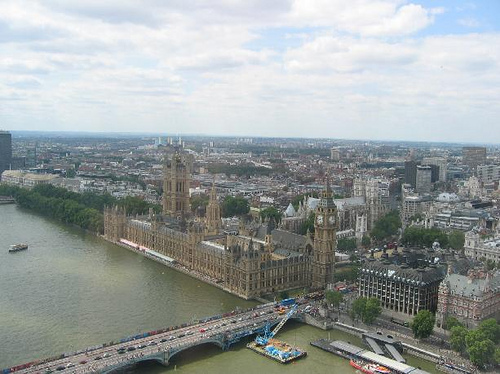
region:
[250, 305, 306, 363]
a tower crane working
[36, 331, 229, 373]
a very busy bridge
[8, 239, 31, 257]
a boat across the river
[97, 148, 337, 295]
a majestic castle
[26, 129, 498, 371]
an aerial view of the city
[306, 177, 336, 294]
a very high tower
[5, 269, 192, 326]
a great volume river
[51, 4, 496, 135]
a sky with many clouds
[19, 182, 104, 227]
bushes in the middle of the city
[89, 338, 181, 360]
a line of cars crossing the bridge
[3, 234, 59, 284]
boat in the water from far away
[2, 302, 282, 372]
vehicle bridge over water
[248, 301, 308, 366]
construction barge with a crane on it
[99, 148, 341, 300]
building with older architecture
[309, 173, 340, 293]
very tall clock tower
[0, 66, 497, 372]
large European city on the water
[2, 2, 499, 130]
blue and cloudy sky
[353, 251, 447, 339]
dark colored building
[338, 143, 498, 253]
metropolitan area crowded with buildings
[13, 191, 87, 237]
trees along the water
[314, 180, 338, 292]
Old clock tower with intricate design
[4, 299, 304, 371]
Bridge over river with cars on it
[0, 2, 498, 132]
Many clouds in a blue sky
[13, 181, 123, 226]
Row of trees next to a river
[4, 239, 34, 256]
Boat in a very large river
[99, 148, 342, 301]
Old intricate well designed building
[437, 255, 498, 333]
brick building with a green tile roof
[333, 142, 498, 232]
Many buildings in the background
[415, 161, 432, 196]
Gray building with black top in background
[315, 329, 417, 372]
Loading dock for boats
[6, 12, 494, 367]
An overhead view of London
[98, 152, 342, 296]
This is the Parliament House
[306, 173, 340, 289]
This is Big Ben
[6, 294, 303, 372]
A bridge is over the river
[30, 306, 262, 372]
Traffic is on the bridge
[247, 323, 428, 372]
Barges are on the river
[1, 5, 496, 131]
The sky is cloudy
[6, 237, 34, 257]
A boat is on the river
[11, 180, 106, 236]
Trees are growing along the river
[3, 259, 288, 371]
The river is green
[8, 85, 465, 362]
This scene is in England.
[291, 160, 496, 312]
This is part of London.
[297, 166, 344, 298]
This is Big Ben.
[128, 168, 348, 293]
This is a historical monument.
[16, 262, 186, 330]
The water is green.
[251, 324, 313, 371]
This is a crane barge.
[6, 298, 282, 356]
This is a bridge.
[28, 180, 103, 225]
There are trees along the water.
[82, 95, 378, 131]
The sky is overcast.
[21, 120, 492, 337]
This is a big city.